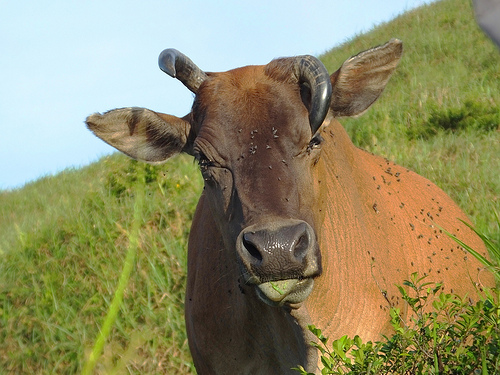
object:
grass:
[0, 0, 500, 375]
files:
[265, 143, 273, 149]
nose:
[234, 219, 315, 274]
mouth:
[247, 270, 319, 311]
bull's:
[256, 277, 303, 302]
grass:
[270, 282, 283, 296]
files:
[373, 207, 381, 214]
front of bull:
[219, 209, 500, 375]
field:
[0, 0, 500, 375]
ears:
[81, 105, 191, 161]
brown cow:
[87, 38, 500, 375]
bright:
[0, 0, 429, 196]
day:
[0, 0, 500, 375]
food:
[268, 281, 284, 296]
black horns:
[157, 48, 209, 92]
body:
[184, 122, 487, 375]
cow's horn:
[295, 55, 332, 138]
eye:
[310, 132, 326, 149]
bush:
[303, 271, 500, 375]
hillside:
[0, 0, 500, 375]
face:
[192, 111, 330, 311]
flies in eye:
[200, 160, 206, 166]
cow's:
[233, 216, 322, 285]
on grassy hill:
[437, 16, 500, 130]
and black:
[300, 55, 332, 136]